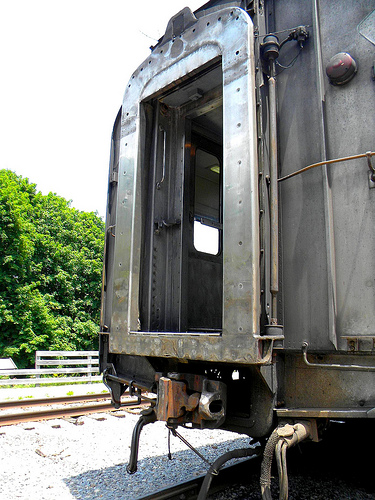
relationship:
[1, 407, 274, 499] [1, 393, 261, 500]
pebbles by tracks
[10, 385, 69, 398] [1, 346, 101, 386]
pebbles by fence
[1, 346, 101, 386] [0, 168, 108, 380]
fence by trees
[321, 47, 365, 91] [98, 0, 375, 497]
red light on train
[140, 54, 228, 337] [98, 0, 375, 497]
door on train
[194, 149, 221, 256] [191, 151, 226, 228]
window with shade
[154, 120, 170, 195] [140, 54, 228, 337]
grab bar on door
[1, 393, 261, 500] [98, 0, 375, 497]
tracks for train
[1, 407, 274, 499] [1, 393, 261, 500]
pebbles between tracks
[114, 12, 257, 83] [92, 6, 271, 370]
holes around doorway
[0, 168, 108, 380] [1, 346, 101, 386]
trees behind fence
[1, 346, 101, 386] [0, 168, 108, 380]
fence in front of trees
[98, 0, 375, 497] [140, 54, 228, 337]
train has door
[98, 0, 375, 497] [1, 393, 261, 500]
train on tracks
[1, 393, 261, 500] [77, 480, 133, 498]
tracks near rocks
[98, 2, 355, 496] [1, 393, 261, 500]
train on tracks